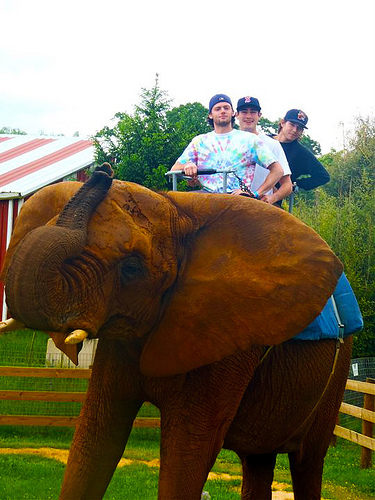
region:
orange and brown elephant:
[57, 165, 338, 492]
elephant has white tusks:
[57, 290, 109, 361]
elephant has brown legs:
[54, 360, 231, 498]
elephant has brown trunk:
[13, 196, 125, 316]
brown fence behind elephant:
[6, 360, 67, 443]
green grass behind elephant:
[15, 443, 66, 489]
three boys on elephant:
[192, 89, 329, 242]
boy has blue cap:
[208, 84, 233, 117]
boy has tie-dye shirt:
[197, 124, 262, 195]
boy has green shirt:
[268, 127, 318, 202]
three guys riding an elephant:
[1, 90, 370, 498]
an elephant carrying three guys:
[2, 93, 369, 498]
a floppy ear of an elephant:
[137, 188, 345, 381]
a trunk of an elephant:
[2, 160, 115, 337]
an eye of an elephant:
[120, 257, 143, 279]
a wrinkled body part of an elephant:
[271, 356, 310, 406]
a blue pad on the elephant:
[292, 268, 366, 343]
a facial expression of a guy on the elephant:
[238, 107, 259, 128]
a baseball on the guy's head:
[283, 108, 311, 130]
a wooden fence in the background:
[333, 376, 373, 470]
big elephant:
[0, 164, 372, 499]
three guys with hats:
[167, 76, 338, 207]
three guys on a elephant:
[4, 75, 372, 498]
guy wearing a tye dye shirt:
[169, 93, 280, 198]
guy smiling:
[234, 95, 274, 131]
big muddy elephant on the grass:
[4, 160, 373, 498]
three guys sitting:
[160, 89, 334, 211]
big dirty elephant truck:
[0, 160, 116, 350]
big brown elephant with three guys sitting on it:
[0, 85, 363, 497]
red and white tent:
[2, 118, 103, 187]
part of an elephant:
[304, 428, 322, 439]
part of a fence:
[351, 402, 356, 429]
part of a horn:
[70, 327, 92, 357]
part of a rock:
[207, 488, 216, 494]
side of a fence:
[333, 422, 339, 433]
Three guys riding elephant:
[0, 47, 358, 497]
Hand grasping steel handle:
[166, 164, 236, 191]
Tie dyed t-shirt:
[178, 130, 274, 193]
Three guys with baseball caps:
[197, 89, 311, 142]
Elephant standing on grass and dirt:
[2, 426, 372, 499]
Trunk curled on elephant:
[0, 161, 112, 328]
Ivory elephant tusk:
[60, 330, 88, 346]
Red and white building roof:
[0, 127, 116, 199]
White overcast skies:
[0, 0, 373, 94]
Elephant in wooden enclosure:
[5, 185, 373, 498]